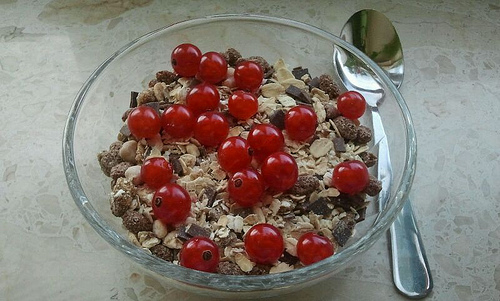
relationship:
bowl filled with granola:
[62, 10, 419, 299] [96, 47, 383, 275]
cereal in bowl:
[100, 42, 380, 274] [62, 10, 419, 299]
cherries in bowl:
[125, 41, 370, 273] [62, 10, 419, 299]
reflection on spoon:
[332, 22, 384, 97] [333, 7, 435, 298]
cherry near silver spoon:
[331, 152, 377, 191] [363, 195, 439, 287]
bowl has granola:
[62, 10, 419, 299] [96, 47, 383, 275]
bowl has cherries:
[62, 10, 419, 299] [125, 41, 370, 273]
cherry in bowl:
[130, 108, 157, 140] [62, 10, 419, 299]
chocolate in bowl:
[282, 75, 309, 97] [62, 10, 419, 299]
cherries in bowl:
[262, 153, 294, 188] [72, 14, 420, 279]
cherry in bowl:
[331, 152, 377, 191] [72, 14, 420, 279]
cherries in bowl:
[220, 144, 247, 167] [72, 14, 420, 279]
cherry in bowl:
[243, 222, 284, 264] [72, 14, 420, 279]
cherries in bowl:
[155, 182, 186, 222] [72, 14, 420, 279]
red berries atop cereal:
[217, 123, 296, 207] [329, 119, 378, 162]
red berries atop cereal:
[127, 82, 228, 146] [270, 58, 315, 100]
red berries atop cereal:
[333, 160, 368, 194] [329, 119, 378, 162]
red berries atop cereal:
[141, 157, 191, 222] [270, 58, 315, 100]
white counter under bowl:
[1, 4, 498, 295] [62, 10, 419, 299]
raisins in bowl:
[150, 241, 181, 260] [62, 10, 419, 299]